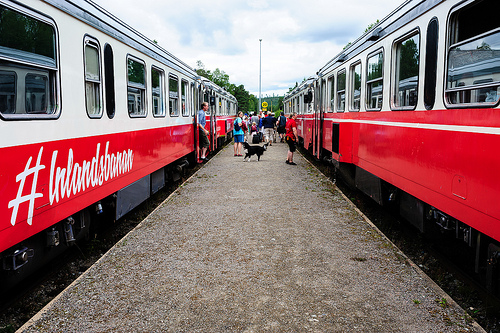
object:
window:
[84, 83, 104, 120]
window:
[0, 60, 58, 115]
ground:
[0, 143, 500, 332]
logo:
[9, 140, 135, 229]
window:
[104, 45, 115, 117]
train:
[0, 0, 237, 286]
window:
[152, 93, 162, 116]